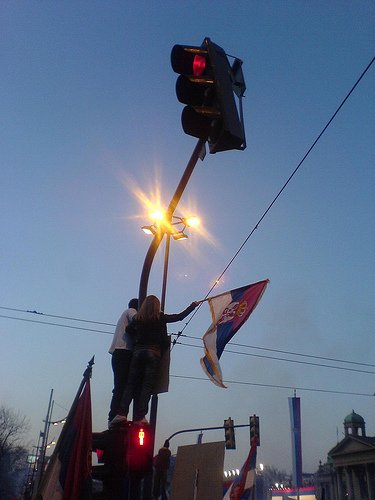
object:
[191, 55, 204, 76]
light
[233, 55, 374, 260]
cable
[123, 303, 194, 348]
shirt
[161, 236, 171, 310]
pole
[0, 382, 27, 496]
tree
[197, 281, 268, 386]
flag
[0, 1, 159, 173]
sky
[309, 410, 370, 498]
building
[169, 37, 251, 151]
signal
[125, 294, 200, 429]
woman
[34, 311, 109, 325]
line